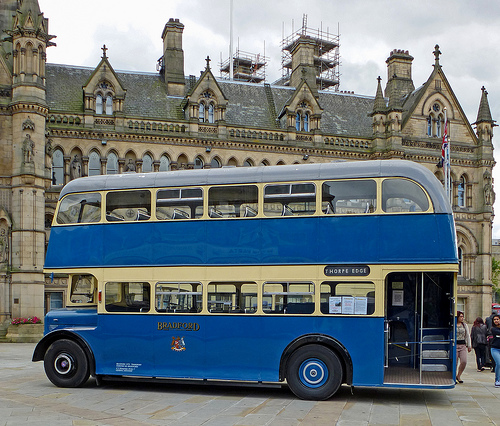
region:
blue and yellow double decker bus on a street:
[30, 156, 456, 401]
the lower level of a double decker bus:
[28, 265, 458, 397]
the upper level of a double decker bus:
[40, 158, 465, 264]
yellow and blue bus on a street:
[30, 155, 460, 397]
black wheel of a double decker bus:
[282, 335, 349, 402]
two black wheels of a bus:
[41, 330, 351, 402]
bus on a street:
[30, 158, 462, 402]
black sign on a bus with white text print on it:
[325, 263, 370, 275]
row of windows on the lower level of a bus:
[98, 276, 377, 314]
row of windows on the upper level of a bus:
[49, 173, 436, 230]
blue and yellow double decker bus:
[70, 167, 395, 391]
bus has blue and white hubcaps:
[280, 343, 367, 390]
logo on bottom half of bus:
[146, 307, 211, 358]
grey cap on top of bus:
[113, 166, 459, 212]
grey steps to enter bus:
[375, 254, 456, 413]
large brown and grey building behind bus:
[16, 36, 495, 297]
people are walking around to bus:
[451, 267, 494, 355]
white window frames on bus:
[131, 181, 337, 231]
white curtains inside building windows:
[93, 81, 228, 141]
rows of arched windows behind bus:
[32, 115, 317, 182]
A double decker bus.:
[20, 148, 455, 421]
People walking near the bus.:
[456, 301, 497, 397]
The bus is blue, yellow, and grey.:
[30, 160, 466, 396]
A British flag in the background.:
[426, 95, 456, 173]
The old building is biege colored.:
[1, 5, 496, 341]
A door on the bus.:
[376, 265, 452, 385]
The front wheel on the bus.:
[40, 334, 90, 389]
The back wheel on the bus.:
[280, 341, 341, 402]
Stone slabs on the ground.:
[86, 390, 272, 423]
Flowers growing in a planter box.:
[10, 312, 42, 327]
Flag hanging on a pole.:
[432, 109, 454, 168]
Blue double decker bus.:
[28, 159, 465, 404]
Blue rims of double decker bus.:
[296, 358, 332, 390]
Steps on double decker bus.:
[420, 322, 451, 375]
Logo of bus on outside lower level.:
[155, 319, 205, 354]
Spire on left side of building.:
[3, 1, 58, 107]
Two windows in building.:
[92, 90, 118, 116]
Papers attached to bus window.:
[327, 295, 371, 317]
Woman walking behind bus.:
[456, 309, 473, 387]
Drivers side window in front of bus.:
[67, 276, 97, 308]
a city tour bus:
[36, 159, 454, 397]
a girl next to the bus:
[455, 311, 468, 388]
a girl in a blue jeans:
[485, 316, 496, 383]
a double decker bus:
[34, 167, 455, 395]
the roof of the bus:
[60, 161, 426, 187]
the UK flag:
[440, 117, 451, 175]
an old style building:
[7, 41, 493, 158]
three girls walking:
[455, 310, 497, 381]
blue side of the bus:
[47, 223, 449, 258]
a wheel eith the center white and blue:
[287, 344, 340, 401]